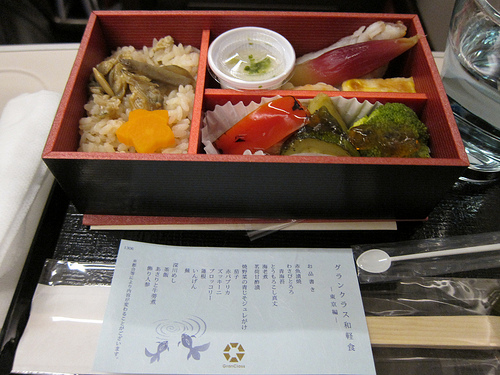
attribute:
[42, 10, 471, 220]
box — asian, red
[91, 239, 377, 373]
paper — white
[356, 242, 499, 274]
utensil — white, small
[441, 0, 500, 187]
glass — transparent, tall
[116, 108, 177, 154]
star — orange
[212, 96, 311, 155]
tomato — red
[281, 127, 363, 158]
vegetable — green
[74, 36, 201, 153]
rice — white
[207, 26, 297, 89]
container — white, small, plastic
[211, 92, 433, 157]
vegetables — fried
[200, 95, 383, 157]
paper — white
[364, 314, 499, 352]
wood — brown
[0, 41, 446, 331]
table — white